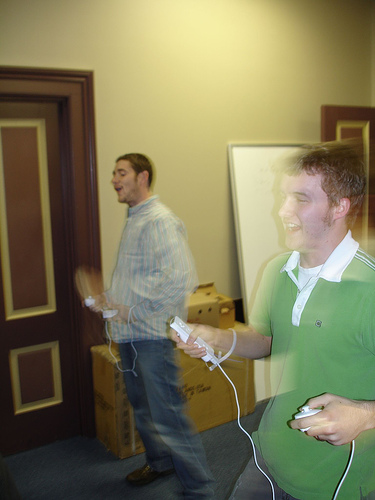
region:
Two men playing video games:
[78, 144, 373, 498]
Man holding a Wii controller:
[166, 142, 373, 497]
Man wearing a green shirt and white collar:
[168, 143, 373, 499]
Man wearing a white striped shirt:
[80, 146, 218, 496]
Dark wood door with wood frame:
[1, 66, 108, 458]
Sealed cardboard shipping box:
[87, 316, 253, 460]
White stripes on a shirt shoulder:
[352, 247, 373, 277]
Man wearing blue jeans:
[78, 150, 218, 498]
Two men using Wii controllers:
[79, 146, 373, 498]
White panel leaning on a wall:
[223, 138, 328, 406]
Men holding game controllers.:
[39, 131, 371, 352]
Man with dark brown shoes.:
[101, 411, 209, 486]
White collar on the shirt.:
[269, 247, 370, 330]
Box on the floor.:
[56, 326, 353, 499]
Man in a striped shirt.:
[36, 114, 298, 347]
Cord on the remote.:
[203, 364, 345, 485]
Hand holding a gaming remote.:
[278, 374, 356, 464]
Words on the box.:
[137, 356, 231, 426]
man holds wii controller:
[76, 150, 222, 498]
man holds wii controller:
[163, 138, 374, 498]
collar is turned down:
[282, 230, 358, 285]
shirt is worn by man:
[251, 232, 373, 498]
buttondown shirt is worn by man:
[102, 193, 192, 340]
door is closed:
[0, 66, 95, 462]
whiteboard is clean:
[225, 140, 321, 400]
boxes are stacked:
[90, 278, 255, 452]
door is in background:
[318, 101, 372, 259]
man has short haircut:
[111, 153, 153, 206]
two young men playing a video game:
[83, 143, 372, 496]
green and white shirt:
[247, 230, 371, 496]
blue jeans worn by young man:
[115, 338, 211, 496]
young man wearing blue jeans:
[72, 152, 219, 493]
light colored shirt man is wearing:
[101, 195, 191, 338]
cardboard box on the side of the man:
[87, 318, 250, 457]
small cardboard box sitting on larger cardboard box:
[180, 285, 231, 324]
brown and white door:
[2, 66, 109, 453]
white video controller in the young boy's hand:
[163, 311, 211, 358]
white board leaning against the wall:
[226, 144, 310, 400]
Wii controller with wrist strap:
[161, 302, 251, 383]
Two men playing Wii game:
[65, 146, 373, 449]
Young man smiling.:
[266, 130, 368, 253]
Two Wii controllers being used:
[64, 264, 266, 371]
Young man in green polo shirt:
[263, 149, 364, 487]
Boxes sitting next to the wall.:
[181, 288, 264, 433]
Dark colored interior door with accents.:
[1, 67, 96, 443]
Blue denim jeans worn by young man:
[114, 333, 212, 498]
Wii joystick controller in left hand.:
[288, 389, 346, 446]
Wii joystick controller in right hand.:
[76, 284, 126, 331]